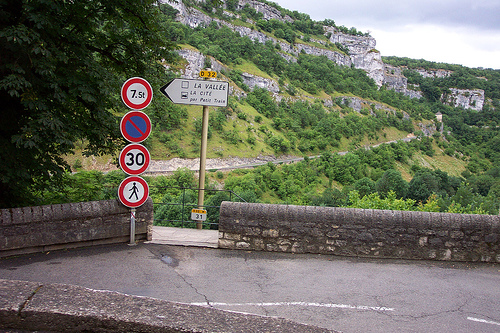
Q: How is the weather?
A: It is cloudy.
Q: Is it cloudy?
A: Yes, it is cloudy.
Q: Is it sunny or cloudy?
A: It is cloudy.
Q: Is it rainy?
A: No, it is cloudy.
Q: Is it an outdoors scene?
A: Yes, it is outdoors.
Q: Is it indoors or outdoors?
A: It is outdoors.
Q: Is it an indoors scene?
A: No, it is outdoors.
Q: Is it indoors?
A: No, it is outdoors.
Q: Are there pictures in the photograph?
A: No, there are no pictures.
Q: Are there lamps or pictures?
A: No, there are no pictures or lamps.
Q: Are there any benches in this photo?
A: No, there are no benches.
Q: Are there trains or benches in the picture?
A: No, there are no benches or trains.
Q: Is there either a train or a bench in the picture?
A: No, there are no benches or trains.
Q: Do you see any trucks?
A: No, there are no trucks.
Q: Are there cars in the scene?
A: No, there are no cars.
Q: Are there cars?
A: No, there are no cars.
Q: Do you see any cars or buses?
A: No, there are no cars or buses.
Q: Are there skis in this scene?
A: No, there are no skis.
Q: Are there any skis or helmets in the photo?
A: No, there are no skis or helmets.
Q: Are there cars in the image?
A: No, there are no cars.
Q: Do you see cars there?
A: No, there are no cars.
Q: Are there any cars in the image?
A: No, there are no cars.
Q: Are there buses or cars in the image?
A: No, there are no cars or buses.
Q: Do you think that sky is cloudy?
A: Yes, the sky is cloudy.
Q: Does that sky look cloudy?
A: Yes, the sky is cloudy.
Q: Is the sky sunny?
A: No, the sky is cloudy.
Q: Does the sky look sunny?
A: No, the sky is cloudy.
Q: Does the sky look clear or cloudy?
A: The sky is cloudy.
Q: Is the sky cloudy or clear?
A: The sky is cloudy.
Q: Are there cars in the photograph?
A: No, there are no cars.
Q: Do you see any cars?
A: No, there are no cars.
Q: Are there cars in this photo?
A: No, there are no cars.